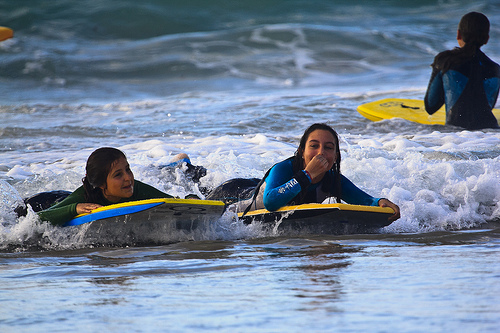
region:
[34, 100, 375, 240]
these are two ladies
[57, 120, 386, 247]
the ladies are sea surfing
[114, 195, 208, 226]
this is a surf board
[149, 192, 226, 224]
the surf board is yellow in color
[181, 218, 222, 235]
the water is splashy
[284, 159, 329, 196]
this is the hand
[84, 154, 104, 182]
the hair is wet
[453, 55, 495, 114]
the costume is black in color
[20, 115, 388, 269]
two people laying on surfboards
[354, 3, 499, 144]
person standing next to a surfboard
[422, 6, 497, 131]
person standing in the water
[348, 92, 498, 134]
yellow board laying on the water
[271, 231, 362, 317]
faint reflection in the water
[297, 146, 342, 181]
hand lifted up to the face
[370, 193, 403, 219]
hand on the edge of the surfboard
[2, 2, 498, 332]
body of water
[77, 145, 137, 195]
head is turned to the side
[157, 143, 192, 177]
foot sticking out of the water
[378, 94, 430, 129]
the surbaord is yellow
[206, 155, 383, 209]
the woman is on the surfboard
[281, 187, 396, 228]
the board is yellow and black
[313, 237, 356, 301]
reflection is in the water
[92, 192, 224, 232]
the surfboard is yellow and blue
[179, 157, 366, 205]
the swimsuit is wet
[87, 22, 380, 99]
waves are in the water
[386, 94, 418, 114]
logo is on the boat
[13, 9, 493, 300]
people in the water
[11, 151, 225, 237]
person on a surf board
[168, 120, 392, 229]
person on a surf board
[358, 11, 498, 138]
person next to surf board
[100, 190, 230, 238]
yellow and blue surf board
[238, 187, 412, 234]
surf board that is yellow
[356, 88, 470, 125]
yellow surf board in water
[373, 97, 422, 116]
image on the board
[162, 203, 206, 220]
image on bottom of board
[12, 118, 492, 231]
white water around surfer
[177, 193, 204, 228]
part of a board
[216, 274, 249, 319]
part of a water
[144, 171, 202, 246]
part f a board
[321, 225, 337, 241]
part of a splash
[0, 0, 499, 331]
A group of young surfers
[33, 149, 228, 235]
The female surfer on the left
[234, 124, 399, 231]
The female surfer in the middle.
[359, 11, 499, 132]
The young surfer on the extreme right.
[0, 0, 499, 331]
The clear waters of the sea.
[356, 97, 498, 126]
The yellow surfing board on the right.